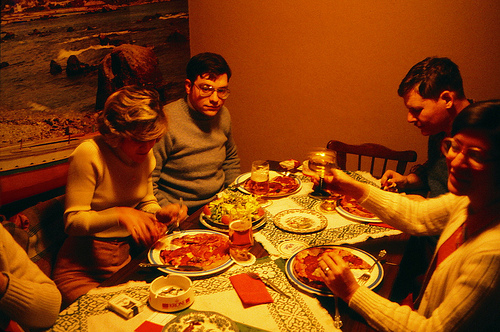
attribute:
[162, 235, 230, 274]
pizza — small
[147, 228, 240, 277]
plate — white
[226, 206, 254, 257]
glass — half full of beer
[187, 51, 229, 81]
hair — brunette, dark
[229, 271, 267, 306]
napkin — red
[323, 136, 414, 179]
chair — wooden, empty, spindled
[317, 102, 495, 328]
woman — toasting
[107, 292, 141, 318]
cigarettes — open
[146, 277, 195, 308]
ashtray — white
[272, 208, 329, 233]
plate — empty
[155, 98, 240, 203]
sweater — gray, brown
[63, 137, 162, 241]
sweater — long sleeve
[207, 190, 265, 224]
salad — italian, untouched, large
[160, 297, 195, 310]
lettering — red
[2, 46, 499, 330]
family — eating italian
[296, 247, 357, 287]
pizza — dinner